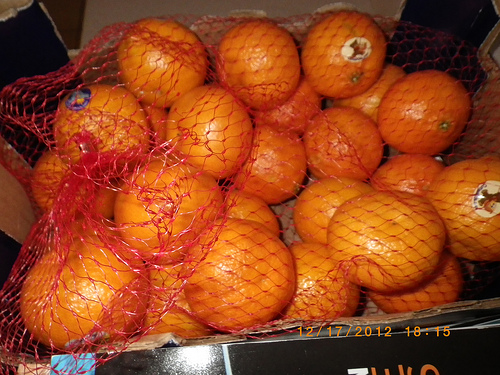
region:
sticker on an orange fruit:
[339, 36, 374, 73]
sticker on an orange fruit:
[332, 31, 387, 106]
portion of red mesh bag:
[5, 62, 102, 259]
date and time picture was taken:
[291, 317, 452, 342]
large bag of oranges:
[23, 19, 499, 329]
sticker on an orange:
[66, 81, 94, 114]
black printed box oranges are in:
[25, 311, 497, 373]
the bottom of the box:
[251, 190, 325, 257]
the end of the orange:
[431, 115, 455, 137]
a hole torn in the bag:
[86, 143, 170, 240]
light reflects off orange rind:
[64, 257, 130, 327]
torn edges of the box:
[2, 0, 84, 75]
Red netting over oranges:
[18, 11, 470, 340]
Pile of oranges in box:
[36, 36, 461, 318]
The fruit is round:
[32, 35, 447, 330]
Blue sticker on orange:
[54, 72, 117, 122]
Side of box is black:
[73, 310, 491, 368]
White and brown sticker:
[334, 29, 399, 72]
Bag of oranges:
[21, 36, 443, 329]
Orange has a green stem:
[336, 65, 369, 91]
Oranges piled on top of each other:
[18, 34, 483, 329]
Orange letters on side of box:
[333, 354, 439, 372]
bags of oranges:
[11, 12, 496, 363]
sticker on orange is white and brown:
[335, 27, 377, 71]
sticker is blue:
[57, 78, 99, 113]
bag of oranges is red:
[0, 11, 264, 373]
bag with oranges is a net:
[20, 71, 175, 253]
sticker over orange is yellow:
[461, 175, 496, 220]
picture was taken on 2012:
[285, 310, 456, 360]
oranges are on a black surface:
[3, 270, 496, 373]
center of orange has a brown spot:
[435, 110, 455, 133]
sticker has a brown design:
[337, 28, 379, 72]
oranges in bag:
[53, 23, 398, 285]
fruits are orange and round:
[162, 103, 432, 291]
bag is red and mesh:
[66, 55, 421, 320]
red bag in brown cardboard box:
[48, 31, 395, 332]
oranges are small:
[287, 15, 392, 97]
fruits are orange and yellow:
[73, 18, 412, 292]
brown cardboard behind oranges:
[11, 16, 62, 216]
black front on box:
[82, 324, 329, 370]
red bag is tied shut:
[0, 103, 170, 283]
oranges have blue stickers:
[45, 72, 107, 122]